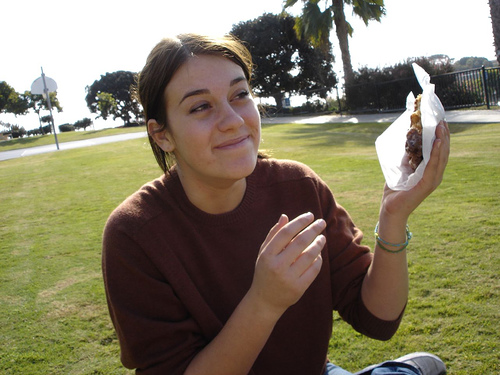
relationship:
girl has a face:
[127, 20, 377, 318] [172, 74, 264, 186]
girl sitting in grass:
[127, 20, 377, 318] [437, 249, 475, 304]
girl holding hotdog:
[98, 32, 452, 375] [404, 94, 427, 174]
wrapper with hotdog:
[376, 133, 397, 177] [404, 94, 427, 174]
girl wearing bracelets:
[98, 32, 452, 375] [373, 227, 416, 259]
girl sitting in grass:
[98, 32, 452, 375] [437, 249, 475, 304]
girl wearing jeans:
[98, 32, 452, 375] [350, 366, 413, 373]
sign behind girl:
[284, 97, 294, 107] [98, 32, 452, 375]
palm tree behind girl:
[305, 2, 363, 82] [98, 32, 452, 375]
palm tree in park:
[305, 2, 363, 82] [11, 9, 500, 364]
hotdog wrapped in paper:
[404, 94, 427, 174] [404, 60, 442, 112]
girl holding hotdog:
[98, 32, 452, 375] [411, 100, 421, 143]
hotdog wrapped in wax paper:
[411, 100, 421, 143] [413, 62, 434, 109]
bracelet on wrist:
[381, 244, 406, 256] [380, 217, 411, 237]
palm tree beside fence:
[305, 2, 363, 82] [455, 71, 498, 105]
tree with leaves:
[352, 66, 390, 111] [293, 12, 333, 51]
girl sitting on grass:
[127, 20, 377, 318] [437, 249, 475, 304]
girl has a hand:
[98, 32, 452, 375] [260, 209, 335, 291]